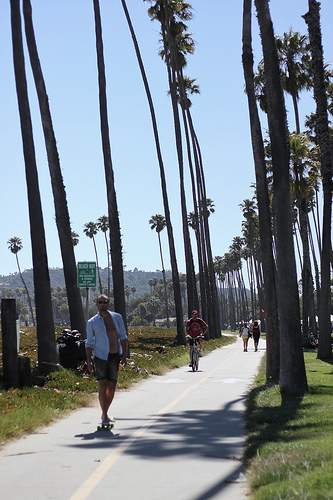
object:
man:
[85, 293, 129, 425]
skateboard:
[96, 418, 114, 434]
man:
[183, 309, 210, 368]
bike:
[185, 333, 204, 372]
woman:
[239, 322, 251, 353]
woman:
[251, 317, 260, 352]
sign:
[77, 261, 99, 290]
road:
[119, 392, 238, 497]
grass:
[279, 430, 330, 499]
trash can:
[56, 326, 86, 370]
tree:
[11, 29, 65, 384]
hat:
[191, 309, 198, 315]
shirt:
[86, 311, 128, 361]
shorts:
[92, 352, 121, 383]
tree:
[253, 0, 314, 400]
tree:
[241, 0, 282, 385]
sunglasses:
[97, 299, 110, 305]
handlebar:
[183, 335, 193, 340]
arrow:
[212, 377, 248, 385]